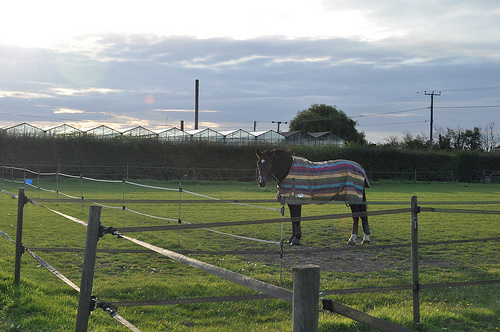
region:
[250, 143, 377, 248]
Horse wearing multi-color striped cover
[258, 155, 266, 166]
White spot on horse's head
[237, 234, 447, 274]
Patch where grass is not growing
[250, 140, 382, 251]
Horse standing in field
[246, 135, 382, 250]
the horse covered with blanket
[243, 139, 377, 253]
the horse is color brown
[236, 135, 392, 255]
the horse is enclosed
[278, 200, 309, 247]
front legs of horse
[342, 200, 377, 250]
back legs of horse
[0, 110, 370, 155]
the roof of building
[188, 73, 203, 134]
a pole behind a building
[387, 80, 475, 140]
electric pole holding wires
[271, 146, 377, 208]
a multicolored blanket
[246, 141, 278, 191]
a white spot on front of horse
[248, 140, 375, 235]
brown horse with blanket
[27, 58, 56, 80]
white clouds in blue sky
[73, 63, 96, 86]
white clouds in blue sky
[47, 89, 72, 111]
white clouds in blue sky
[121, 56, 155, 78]
white clouds in blue sky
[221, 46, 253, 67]
white clouds in blue sky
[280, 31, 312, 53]
white clouds in blue sky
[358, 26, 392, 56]
white clouds in blue sky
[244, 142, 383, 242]
brown hose covered by blanket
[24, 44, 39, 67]
white clouds in blue sky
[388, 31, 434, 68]
white clouds in blue sky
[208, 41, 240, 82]
white clouds in blue sky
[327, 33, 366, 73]
white clouds in blue sky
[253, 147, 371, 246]
brown horse wearing blanket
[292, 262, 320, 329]
brown wooden fence post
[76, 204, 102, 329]
brown wooden fence post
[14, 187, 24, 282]
brown wooden fence post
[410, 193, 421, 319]
brown wooden fence post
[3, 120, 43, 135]
roof of a greenhouse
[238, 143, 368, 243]
brown horse in blanket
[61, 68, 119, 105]
white clouds in blue sky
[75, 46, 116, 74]
white clouds in blue sky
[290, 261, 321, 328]
wooden post on horse fence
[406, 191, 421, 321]
wooden post on horse fence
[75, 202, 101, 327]
wooden post on horse fence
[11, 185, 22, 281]
wooden post on horse fence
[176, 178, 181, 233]
wooden post on horse fence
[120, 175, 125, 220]
wooden post on horse fence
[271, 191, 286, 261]
wooden post on horse fence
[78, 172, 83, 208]
wooden post on horse fence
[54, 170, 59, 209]
wooden post on horse fence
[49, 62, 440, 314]
this is a farm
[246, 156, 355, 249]
the horse is standing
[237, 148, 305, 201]
the horse is dark brown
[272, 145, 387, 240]
the horse is wearing a blanket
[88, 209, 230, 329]
the fence is brown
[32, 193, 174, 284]
the fence is wooden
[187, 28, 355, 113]
the clouds are overhead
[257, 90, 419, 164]
the trees are in the background